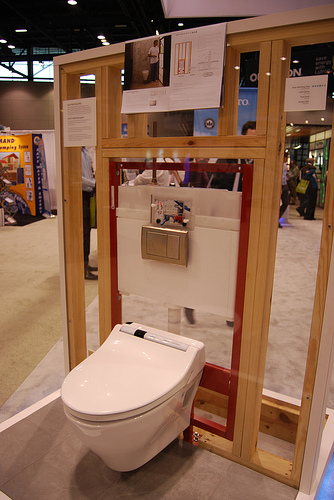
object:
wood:
[250, 185, 272, 267]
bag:
[295, 179, 310, 195]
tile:
[136, 447, 299, 500]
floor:
[186, 462, 242, 500]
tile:
[268, 307, 298, 386]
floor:
[3, 445, 28, 497]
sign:
[284, 74, 329, 112]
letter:
[292, 84, 326, 103]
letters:
[0, 137, 15, 143]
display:
[53, 0, 334, 500]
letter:
[0, 138, 15, 143]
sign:
[0, 132, 37, 216]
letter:
[0, 145, 28, 150]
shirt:
[81, 147, 96, 192]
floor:
[3, 318, 36, 376]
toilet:
[60, 321, 206, 472]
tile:
[0, 434, 120, 500]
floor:
[281, 251, 298, 310]